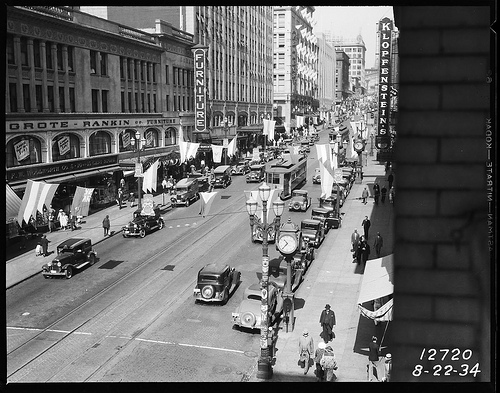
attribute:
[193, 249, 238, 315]
vehicle — here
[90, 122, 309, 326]
road — here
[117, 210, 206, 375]
street — here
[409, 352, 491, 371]
date — here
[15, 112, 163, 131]
sign — here, large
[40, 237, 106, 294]
car — black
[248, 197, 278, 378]
post — metal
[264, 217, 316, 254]
clock — here, round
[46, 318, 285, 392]
line — white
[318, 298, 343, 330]
man — walking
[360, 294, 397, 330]
flag — hanging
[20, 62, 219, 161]
building — large, brick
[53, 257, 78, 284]
headlight — here